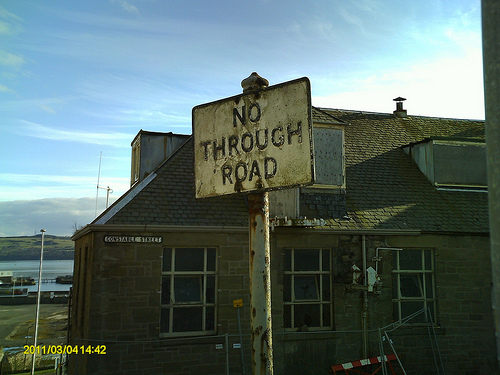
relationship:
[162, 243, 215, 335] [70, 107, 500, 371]
window on side of house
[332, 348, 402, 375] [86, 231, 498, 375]
construction sign on side of wall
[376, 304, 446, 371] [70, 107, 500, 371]
pipes coming out of building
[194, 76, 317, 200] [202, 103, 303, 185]
sign says no through road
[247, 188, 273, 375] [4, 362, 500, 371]
pole in ground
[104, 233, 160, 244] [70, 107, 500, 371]
sign on side of house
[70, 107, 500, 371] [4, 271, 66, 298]
house near shore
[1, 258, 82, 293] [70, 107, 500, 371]
water behind house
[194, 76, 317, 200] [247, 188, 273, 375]
sign on top of pole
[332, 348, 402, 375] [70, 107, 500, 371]
construction sign by house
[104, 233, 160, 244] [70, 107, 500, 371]
sign on side of building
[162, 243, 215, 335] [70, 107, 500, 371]
window on side of buildig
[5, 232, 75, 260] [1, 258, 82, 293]
hill behind water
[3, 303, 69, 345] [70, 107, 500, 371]
field behind house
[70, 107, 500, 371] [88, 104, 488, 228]
house has roof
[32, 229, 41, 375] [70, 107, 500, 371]
pole behind house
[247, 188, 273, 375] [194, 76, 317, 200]
pole holding sign